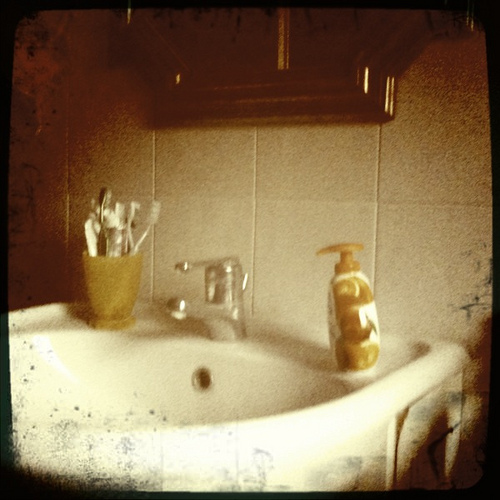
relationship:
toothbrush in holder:
[135, 200, 163, 252] [78, 242, 141, 329]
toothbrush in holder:
[121, 199, 138, 253] [78, 242, 141, 329]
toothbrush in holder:
[95, 184, 109, 244] [78, 242, 141, 329]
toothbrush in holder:
[115, 200, 129, 254] [78, 242, 141, 329]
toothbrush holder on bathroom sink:
[81, 246, 144, 329] [0, 306, 465, 495]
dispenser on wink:
[296, 213, 393, 373] [43, 291, 403, 495]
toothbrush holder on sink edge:
[75, 221, 144, 315] [266, 429, 343, 473]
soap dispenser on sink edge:
[310, 232, 386, 369] [266, 429, 343, 473]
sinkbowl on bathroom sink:
[17, 333, 352, 427] [0, 306, 465, 495]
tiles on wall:
[35, 50, 491, 333] [6, 10, 498, 453]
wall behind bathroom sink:
[6, 10, 498, 453] [0, 306, 465, 495]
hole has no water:
[190, 364, 213, 396] [12, 335, 354, 433]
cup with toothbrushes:
[78, 245, 143, 326] [77, 181, 162, 250]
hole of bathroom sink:
[192, 369, 213, 393] [0, 306, 465, 495]